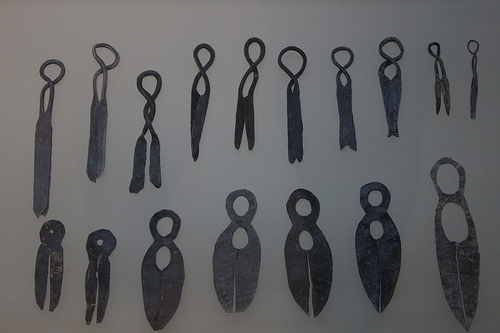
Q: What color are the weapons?
A: Silver.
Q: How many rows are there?
A: 2.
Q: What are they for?
A: Cutting.